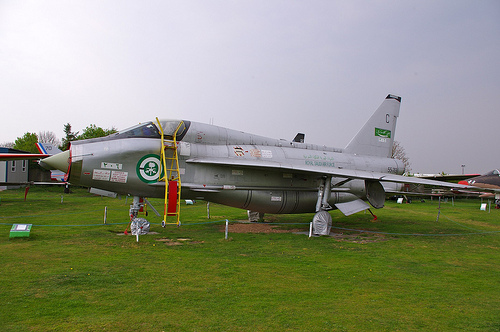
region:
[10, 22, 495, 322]
a scene outside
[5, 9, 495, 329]
a photo at a field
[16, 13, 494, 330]
a scene during the day time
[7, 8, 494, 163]
a white sky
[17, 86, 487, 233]
a silver airplane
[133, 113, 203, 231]
a yellow ladder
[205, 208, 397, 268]
a brown patch on green grass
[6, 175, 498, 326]
a patch of green grass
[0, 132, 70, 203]
a white building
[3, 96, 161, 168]
some green trees in distance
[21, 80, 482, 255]
a retired fighter jet on display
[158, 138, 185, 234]
a yellow ladder up to the cockpit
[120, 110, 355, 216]
the fuselage of a jet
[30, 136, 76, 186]
the intake value of a jet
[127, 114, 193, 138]
the cockpit of a jet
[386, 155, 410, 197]
the thrusters of a jet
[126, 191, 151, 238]
the nose gear of a jet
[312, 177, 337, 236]
the landing gear of a jet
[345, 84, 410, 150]
the tail-fin of a jet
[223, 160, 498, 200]
the wing of a jet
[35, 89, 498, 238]
A small gray plane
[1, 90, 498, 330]
The plane is on green grass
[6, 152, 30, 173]
Two windows on a house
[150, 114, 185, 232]
A yellow colored ladder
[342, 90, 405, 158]
The tail of a plane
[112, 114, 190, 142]
Window on an airplane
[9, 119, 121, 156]
Green leaves on trees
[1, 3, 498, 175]
The sky appears to be overcast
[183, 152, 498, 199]
The wing of a plane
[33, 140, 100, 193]
The nose of the plane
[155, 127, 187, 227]
the yellow ladder on the side of a plane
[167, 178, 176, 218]
a red panel behind the ladder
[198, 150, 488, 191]
the silver wing of a plane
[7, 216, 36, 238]
a green plaque on the ground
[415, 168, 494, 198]
a red plane in the background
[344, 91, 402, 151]
a silver tail fin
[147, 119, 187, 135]
the cockpit of a plane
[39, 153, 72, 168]
the pointed nose of the plane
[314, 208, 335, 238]
the covered wheel of the plane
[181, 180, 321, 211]
the underbelly of the plane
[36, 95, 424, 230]
a large airplane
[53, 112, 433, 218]
an airplane sitting on the grass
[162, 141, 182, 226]
a yellow ladder coming off the airplane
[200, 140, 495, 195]
the wing of the airplane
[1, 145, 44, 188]
a house behind the airplane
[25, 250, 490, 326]
grass in front of the airplane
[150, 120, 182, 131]
the windshield of the airplane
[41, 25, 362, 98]
the grey sky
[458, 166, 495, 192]
the tip of another airplane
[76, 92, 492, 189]
many airplanes on the ground